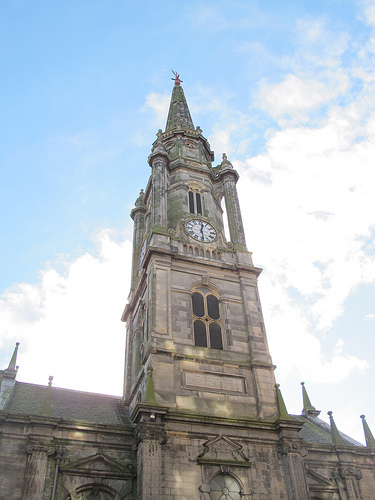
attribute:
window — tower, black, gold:
[191, 287, 220, 350]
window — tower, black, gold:
[187, 186, 204, 213]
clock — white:
[182, 215, 220, 244]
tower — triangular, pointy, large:
[122, 68, 302, 427]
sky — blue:
[3, 21, 361, 402]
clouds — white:
[238, 59, 362, 374]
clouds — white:
[10, 231, 123, 381]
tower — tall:
[116, 66, 283, 418]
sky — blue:
[6, 4, 363, 431]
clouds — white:
[246, 79, 362, 365]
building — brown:
[1, 64, 363, 495]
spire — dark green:
[134, 363, 159, 410]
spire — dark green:
[269, 376, 296, 427]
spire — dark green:
[293, 378, 323, 418]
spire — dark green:
[323, 406, 345, 448]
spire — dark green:
[355, 414, 373, 448]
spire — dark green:
[3, 336, 23, 373]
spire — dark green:
[30, 372, 62, 422]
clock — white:
[189, 218, 219, 238]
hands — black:
[198, 222, 206, 240]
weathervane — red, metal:
[172, 71, 186, 85]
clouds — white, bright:
[11, 233, 126, 394]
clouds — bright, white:
[262, 137, 370, 424]